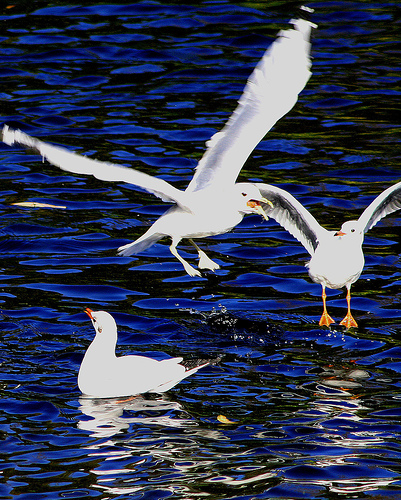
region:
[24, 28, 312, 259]
seagull over the water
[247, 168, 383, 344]
seagull walking on the water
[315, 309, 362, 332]
bird with webbed feet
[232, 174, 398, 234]
bird with its wings open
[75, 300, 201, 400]
white bird on the water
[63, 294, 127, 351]
bird with its head up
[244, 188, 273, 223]
bird with its mouth open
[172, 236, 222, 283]
bird about to land on water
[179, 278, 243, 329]
water splashs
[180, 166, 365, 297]
bird attacking another bird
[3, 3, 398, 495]
surface of water with ripples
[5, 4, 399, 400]
three seagulls on and above water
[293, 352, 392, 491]
reflection of bird on water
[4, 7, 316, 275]
bird with extended wings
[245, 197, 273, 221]
open beak of bird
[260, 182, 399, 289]
wings up on seagull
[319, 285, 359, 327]
two orange legs under bird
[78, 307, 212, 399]
seagull floating in water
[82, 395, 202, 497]
reflection of floating bird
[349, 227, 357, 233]
eye on bird head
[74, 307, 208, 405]
The bird is on the water.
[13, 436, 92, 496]
The water is calm.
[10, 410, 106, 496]
The water is dark in color.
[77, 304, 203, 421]
The bird is white.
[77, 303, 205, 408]
The bird has white feathers.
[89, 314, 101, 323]
The bird has a black eye.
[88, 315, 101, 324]
The birds eye is small.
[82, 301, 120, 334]
The birds beak is orange.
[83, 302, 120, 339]
The birds beak has a sharp point.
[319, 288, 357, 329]
The birds feet are orange.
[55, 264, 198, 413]
bird on the water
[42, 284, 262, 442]
bird on the water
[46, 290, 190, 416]
the bird is white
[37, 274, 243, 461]
the bird is white